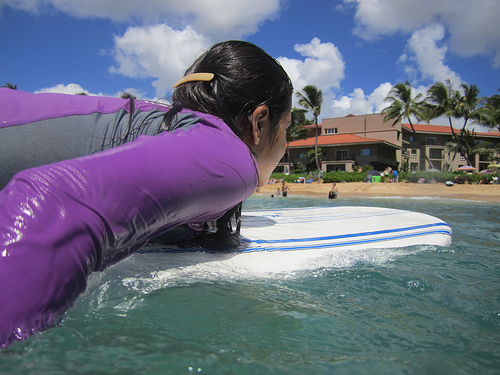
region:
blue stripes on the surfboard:
[140, 212, 473, 266]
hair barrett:
[144, 70, 234, 97]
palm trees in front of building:
[386, 66, 498, 181]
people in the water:
[269, 181, 346, 203]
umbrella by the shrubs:
[454, 159, 474, 182]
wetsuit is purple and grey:
[8, 84, 255, 353]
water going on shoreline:
[367, 185, 481, 202]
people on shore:
[365, 162, 406, 184]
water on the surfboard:
[170, 244, 472, 288]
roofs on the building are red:
[290, 126, 499, 143]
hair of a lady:
[230, 53, 251, 86]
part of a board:
[310, 195, 335, 238]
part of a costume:
[123, 186, 158, 228]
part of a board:
[310, 183, 353, 256]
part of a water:
[383, 262, 420, 334]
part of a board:
[353, 187, 378, 232]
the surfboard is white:
[171, 169, 447, 316]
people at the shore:
[257, 163, 291, 205]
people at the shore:
[270, 163, 370, 210]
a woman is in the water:
[29, 35, 464, 359]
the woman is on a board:
[39, 183, 448, 300]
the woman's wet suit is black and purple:
[7, 66, 227, 328]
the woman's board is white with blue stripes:
[141, 192, 447, 311]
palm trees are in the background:
[296, 83, 498, 169]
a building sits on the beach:
[288, 107, 494, 182]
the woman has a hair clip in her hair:
[169, 63, 211, 96]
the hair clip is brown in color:
[172, 71, 213, 93]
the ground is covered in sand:
[290, 178, 489, 208]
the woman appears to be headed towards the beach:
[96, 46, 479, 312]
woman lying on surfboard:
[3, 20, 458, 333]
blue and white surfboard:
[76, 176, 456, 298]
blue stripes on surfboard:
[135, 219, 452, 258]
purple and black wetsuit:
[1, 75, 261, 351]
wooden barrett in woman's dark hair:
[168, 67, 221, 91]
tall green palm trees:
[385, 75, 495, 167]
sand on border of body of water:
[276, 178, 498, 204]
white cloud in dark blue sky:
[289, 43, 370, 72]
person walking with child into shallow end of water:
[267, 179, 293, 204]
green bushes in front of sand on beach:
[277, 163, 497, 184]